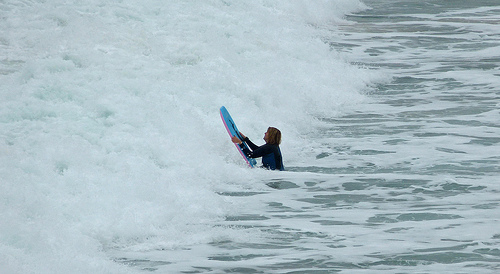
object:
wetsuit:
[240, 136, 285, 170]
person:
[234, 126, 285, 169]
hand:
[230, 134, 239, 143]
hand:
[236, 129, 247, 137]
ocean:
[0, 2, 497, 272]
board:
[217, 104, 256, 170]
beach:
[0, 0, 499, 271]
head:
[261, 128, 283, 145]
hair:
[266, 125, 283, 145]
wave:
[0, 0, 366, 256]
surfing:
[217, 104, 282, 172]